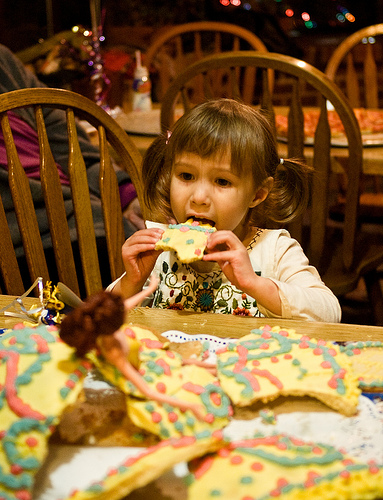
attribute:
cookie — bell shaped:
[152, 210, 218, 270]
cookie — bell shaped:
[210, 317, 363, 417]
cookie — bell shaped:
[103, 323, 234, 440]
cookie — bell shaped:
[0, 316, 93, 498]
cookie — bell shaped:
[193, 429, 380, 498]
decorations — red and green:
[139, 341, 354, 432]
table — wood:
[0, 296, 378, 399]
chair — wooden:
[2, 88, 153, 300]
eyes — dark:
[174, 169, 236, 191]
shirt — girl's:
[106, 228, 341, 323]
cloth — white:
[40, 331, 381, 497]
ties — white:
[275, 153, 290, 167]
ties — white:
[164, 129, 173, 141]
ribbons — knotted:
[7, 278, 62, 324]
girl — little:
[134, 93, 275, 228]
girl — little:
[103, 97, 341, 323]